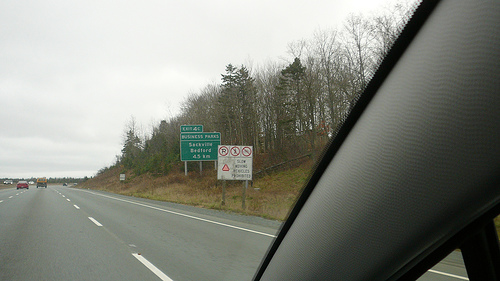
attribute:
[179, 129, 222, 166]
sign — green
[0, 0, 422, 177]
clouds — white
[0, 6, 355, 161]
clouds — white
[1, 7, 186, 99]
clouds — white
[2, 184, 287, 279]
sign — green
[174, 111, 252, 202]
sign — green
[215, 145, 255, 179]
street sign — white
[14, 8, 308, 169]
clouds — white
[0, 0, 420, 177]
sky — blue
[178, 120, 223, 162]
sign — green, white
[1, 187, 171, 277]
lines — white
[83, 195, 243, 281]
lines — white